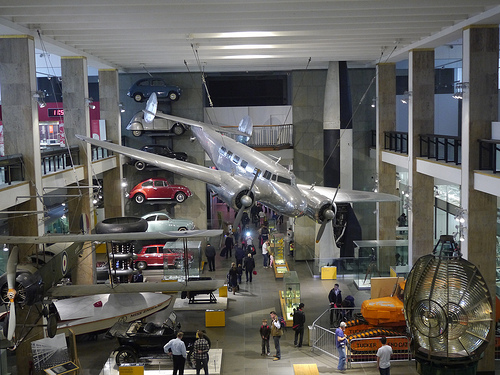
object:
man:
[194, 331, 209, 374]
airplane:
[74, 91, 402, 243]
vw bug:
[126, 77, 183, 102]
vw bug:
[126, 144, 188, 176]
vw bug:
[128, 178, 193, 205]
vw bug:
[140, 212, 195, 233]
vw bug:
[133, 244, 194, 270]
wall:
[118, 65, 454, 239]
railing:
[418, 133, 461, 165]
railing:
[383, 130, 408, 154]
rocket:
[318, 61, 353, 276]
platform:
[369, 130, 500, 174]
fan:
[404, 235, 493, 358]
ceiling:
[2, 2, 497, 73]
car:
[126, 78, 183, 103]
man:
[163, 332, 187, 374]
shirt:
[164, 338, 187, 358]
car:
[132, 244, 194, 270]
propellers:
[231, 168, 340, 244]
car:
[128, 178, 192, 204]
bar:
[40, 145, 81, 175]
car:
[113, 311, 212, 370]